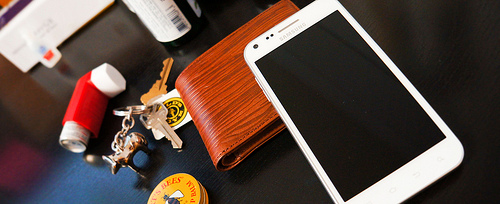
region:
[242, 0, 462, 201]
White digital cellphone on a table.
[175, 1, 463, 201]
White cellphone on top of wallet on a desk.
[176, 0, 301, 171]
Brown wallet underneath a white cellphone.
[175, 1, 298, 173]
Brown wallet on the table.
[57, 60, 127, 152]
Breath inhalant to treat asthma symptoms.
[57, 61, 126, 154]
Red and white breath asthma inhalant.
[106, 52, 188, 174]
Two keys on a key chain.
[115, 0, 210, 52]
Medication bottle on the table.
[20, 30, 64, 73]
Visine eye drops for allergies.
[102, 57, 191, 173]
Keys on a chain between a wallet and inhalant.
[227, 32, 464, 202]
the samsung is on the table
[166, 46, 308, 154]
the wallet is brown in color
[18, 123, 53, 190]
the table is wooden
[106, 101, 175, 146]
the keys are on the table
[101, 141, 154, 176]
the keyholder has an animal statue on it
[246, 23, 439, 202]
the phone is a smart phone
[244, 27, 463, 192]
the phone is shut off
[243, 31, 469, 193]
the make of the phone is samsung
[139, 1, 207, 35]
there is a container on the table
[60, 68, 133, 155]
the inhaler is on the table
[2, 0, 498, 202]
top of person's dresser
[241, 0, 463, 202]
white Samsung cell phone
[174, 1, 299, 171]
woodgrain look man's wallet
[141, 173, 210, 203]
Burt's Bees lip balm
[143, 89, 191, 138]
Gold's Gym key tag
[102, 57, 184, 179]
set of keys on ring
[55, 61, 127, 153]
asthma inhaler with cap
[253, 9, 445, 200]
black cell phone screen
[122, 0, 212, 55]
bottle of liquid medicine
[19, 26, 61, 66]
bottle of eye drops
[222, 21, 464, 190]
A white cell phone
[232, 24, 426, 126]
A cell phone on a wallet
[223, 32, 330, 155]
A brown wallet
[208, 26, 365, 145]
A brown wallet under a white cell phone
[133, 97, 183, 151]
A single key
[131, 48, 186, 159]
Two keys on a table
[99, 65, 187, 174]
Two keys on a key chain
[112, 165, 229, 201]
A yellow tin of lip balm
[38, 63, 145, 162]
A red inhaler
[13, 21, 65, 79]
A bottle of eye drops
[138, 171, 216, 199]
burts bees lip balm container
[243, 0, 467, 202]
white samsung smart phone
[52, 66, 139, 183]
red and white inhaler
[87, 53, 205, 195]
several keys on keychain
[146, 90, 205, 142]
Golds Gym tag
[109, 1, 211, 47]
bottom of bottle sitting on desk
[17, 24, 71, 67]
small bottle of eye drops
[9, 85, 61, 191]
red reflection on desk top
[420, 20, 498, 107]
dark brown wooden desk top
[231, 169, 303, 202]
dark brown wooden desk top